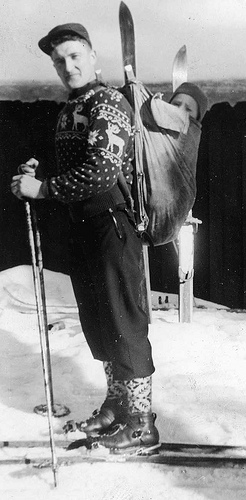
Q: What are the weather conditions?
A: It is sunny.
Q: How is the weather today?
A: It is sunny.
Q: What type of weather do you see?
A: It is sunny.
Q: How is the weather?
A: It is sunny.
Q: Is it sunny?
A: Yes, it is sunny.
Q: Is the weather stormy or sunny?
A: It is sunny.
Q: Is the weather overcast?
A: No, it is sunny.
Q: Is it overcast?
A: No, it is sunny.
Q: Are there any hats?
A: Yes, there is a hat.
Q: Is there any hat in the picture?
A: Yes, there is a hat.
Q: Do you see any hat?
A: Yes, there is a hat.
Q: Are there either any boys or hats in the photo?
A: Yes, there is a hat.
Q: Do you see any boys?
A: No, there are no boys.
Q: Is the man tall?
A: Yes, the man is tall.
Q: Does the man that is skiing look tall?
A: Yes, the man is tall.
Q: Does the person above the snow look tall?
A: Yes, the man is tall.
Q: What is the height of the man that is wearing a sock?
A: The man is tall.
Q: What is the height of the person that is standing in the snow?
A: The man is tall.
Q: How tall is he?
A: The man is tall.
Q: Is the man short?
A: No, the man is tall.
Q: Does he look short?
A: No, the man is tall.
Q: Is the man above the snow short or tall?
A: The man is tall.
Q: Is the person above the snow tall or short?
A: The man is tall.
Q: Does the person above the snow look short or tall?
A: The man is tall.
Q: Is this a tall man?
A: Yes, this is a tall man.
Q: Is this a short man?
A: No, this is a tall man.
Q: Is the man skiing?
A: Yes, the man is skiing.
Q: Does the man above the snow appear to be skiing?
A: Yes, the man is skiing.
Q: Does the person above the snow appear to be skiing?
A: Yes, the man is skiing.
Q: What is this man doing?
A: The man is skiing.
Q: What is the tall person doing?
A: The man is skiing.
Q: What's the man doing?
A: The man is skiing.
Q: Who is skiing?
A: The man is skiing.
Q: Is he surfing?
A: No, the man is skiing.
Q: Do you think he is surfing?
A: No, the man is skiing.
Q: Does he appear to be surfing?
A: No, the man is skiing.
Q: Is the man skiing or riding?
A: The man is skiing.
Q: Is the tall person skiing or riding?
A: The man is skiing.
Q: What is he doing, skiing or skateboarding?
A: The man is skiing.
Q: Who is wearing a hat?
A: The man is wearing a hat.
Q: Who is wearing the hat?
A: The man is wearing a hat.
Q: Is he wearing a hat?
A: Yes, the man is wearing a hat.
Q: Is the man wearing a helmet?
A: No, the man is wearing a hat.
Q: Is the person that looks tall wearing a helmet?
A: No, the man is wearing a hat.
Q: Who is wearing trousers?
A: The man is wearing trousers.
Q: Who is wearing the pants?
A: The man is wearing trousers.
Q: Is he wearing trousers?
A: Yes, the man is wearing trousers.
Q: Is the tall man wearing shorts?
A: No, the man is wearing trousers.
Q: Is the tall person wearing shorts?
A: No, the man is wearing trousers.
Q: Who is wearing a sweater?
A: The man is wearing a sweater.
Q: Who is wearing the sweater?
A: The man is wearing a sweater.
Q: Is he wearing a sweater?
A: Yes, the man is wearing a sweater.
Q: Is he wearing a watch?
A: No, the man is wearing a sweater.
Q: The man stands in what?
A: The man stands in the snow.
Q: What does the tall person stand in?
A: The man stands in the snow.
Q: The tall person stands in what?
A: The man stands in the snow.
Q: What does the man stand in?
A: The man stands in the snow.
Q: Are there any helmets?
A: No, there are no helmets.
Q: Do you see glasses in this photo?
A: No, there are no glasses.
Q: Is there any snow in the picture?
A: Yes, there is snow.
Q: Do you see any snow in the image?
A: Yes, there is snow.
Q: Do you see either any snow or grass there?
A: Yes, there is snow.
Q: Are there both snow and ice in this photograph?
A: No, there is snow but no ice.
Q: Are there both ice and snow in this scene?
A: No, there is snow but no ice.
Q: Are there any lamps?
A: No, there are no lamps.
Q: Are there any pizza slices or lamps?
A: No, there are no lamps or pizza slices.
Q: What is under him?
A: The snow is under the man.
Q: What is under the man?
A: The snow is under the man.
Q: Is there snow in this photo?
A: Yes, there is snow.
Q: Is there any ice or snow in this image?
A: Yes, there is snow.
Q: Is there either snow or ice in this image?
A: Yes, there is snow.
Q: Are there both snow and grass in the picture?
A: No, there is snow but no grass.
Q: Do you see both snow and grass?
A: No, there is snow but no grass.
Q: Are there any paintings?
A: No, there are no paintings.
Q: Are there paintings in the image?
A: No, there are no paintings.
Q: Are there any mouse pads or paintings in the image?
A: No, there are no paintings or mouse pads.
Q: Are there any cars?
A: No, there are no cars.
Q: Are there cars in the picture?
A: No, there are no cars.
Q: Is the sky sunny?
A: Yes, the sky is sunny.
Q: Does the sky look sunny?
A: Yes, the sky is sunny.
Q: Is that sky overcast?
A: No, the sky is sunny.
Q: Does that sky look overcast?
A: No, the sky is sunny.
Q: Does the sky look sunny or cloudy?
A: The sky is sunny.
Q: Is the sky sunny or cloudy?
A: The sky is sunny.